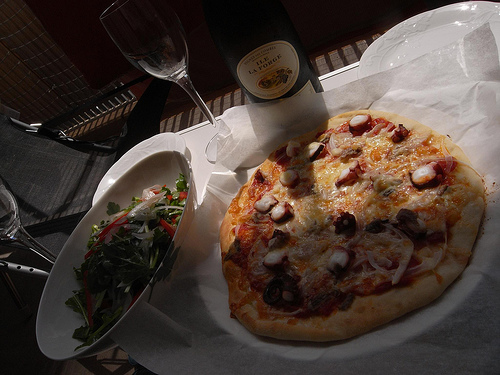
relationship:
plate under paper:
[194, 276, 217, 316] [397, 69, 487, 126]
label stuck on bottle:
[235, 43, 300, 100] [212, 9, 328, 111]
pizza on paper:
[202, 108, 483, 355] [112, 25, 497, 374]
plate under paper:
[357, 0, 498, 80] [195, 21, 497, 239]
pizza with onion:
[202, 108, 483, 355] [408, 160, 436, 187]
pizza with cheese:
[202, 108, 483, 355] [248, 130, 452, 297]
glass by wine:
[100, 1, 242, 161] [203, 0, 324, 104]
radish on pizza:
[407, 156, 439, 189] [202, 108, 483, 355]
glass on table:
[100, 1, 242, 161] [36, 27, 497, 362]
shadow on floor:
[157, 30, 386, 139] [25, 15, 479, 108]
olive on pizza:
[253, 273, 307, 310] [202, 108, 483, 355]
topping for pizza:
[346, 112, 373, 135] [217, 108, 487, 343]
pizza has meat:
[217, 108, 487, 343] [250, 190, 295, 278]